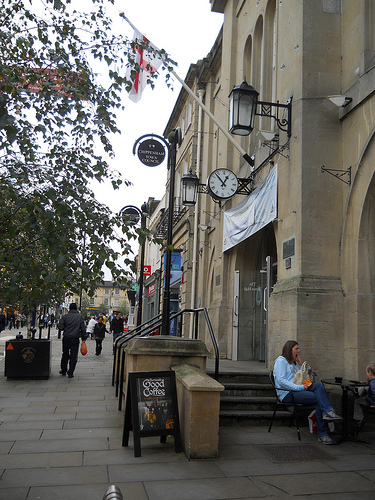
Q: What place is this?
A: It is a sidewalk.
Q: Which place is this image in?
A: It is at the sidewalk.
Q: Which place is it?
A: It is a sidewalk.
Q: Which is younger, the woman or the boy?
A: The boy is younger than the woman.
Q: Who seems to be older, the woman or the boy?
A: The woman is older than the boy.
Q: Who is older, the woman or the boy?
A: The woman is older than the boy.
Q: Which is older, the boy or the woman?
A: The woman is older than the boy.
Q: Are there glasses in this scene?
A: No, there are no glasses.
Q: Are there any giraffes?
A: No, there are no giraffes.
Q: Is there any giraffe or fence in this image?
A: No, there are no giraffes or fences.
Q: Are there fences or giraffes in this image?
A: No, there are no giraffes or fences.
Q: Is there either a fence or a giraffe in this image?
A: No, there are no giraffes or fences.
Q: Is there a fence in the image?
A: No, there are no fences.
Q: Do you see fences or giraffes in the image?
A: No, there are no fences or giraffes.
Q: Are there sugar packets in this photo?
A: No, there are no sugar packets.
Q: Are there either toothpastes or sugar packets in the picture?
A: No, there are no sugar packets or toothpastes.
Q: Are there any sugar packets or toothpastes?
A: No, there are no sugar packets or toothpastes.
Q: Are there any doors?
A: Yes, there is a door.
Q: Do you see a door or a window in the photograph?
A: Yes, there is a door.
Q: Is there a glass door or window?
A: Yes, there is a glass door.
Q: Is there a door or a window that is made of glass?
A: Yes, the door is made of glass.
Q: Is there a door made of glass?
A: Yes, there is a door that is made of glass.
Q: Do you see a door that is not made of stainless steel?
A: Yes, there is a door that is made of glass.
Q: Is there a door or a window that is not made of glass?
A: No, there is a door but it is made of glass.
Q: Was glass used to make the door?
A: Yes, the door is made of glass.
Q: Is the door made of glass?
A: Yes, the door is made of glass.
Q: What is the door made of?
A: The door is made of glass.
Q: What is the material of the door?
A: The door is made of glass.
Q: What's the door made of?
A: The door is made of glass.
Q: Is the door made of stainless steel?
A: No, the door is made of glass.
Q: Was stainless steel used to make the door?
A: No, the door is made of glass.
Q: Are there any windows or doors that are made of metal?
A: No, there is a door but it is made of glass.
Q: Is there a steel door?
A: No, there is a door but it is made of glass.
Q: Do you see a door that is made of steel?
A: No, there is a door but it is made of glass.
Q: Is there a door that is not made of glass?
A: No, there is a door but it is made of glass.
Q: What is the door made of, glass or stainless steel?
A: The door is made of glass.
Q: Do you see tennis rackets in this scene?
A: No, there are no tennis rackets.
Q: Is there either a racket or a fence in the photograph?
A: No, there are no rackets or fences.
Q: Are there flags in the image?
A: Yes, there is a flag.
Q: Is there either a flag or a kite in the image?
A: Yes, there is a flag.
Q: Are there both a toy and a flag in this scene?
A: No, there is a flag but no toys.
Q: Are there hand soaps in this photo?
A: No, there are no hand soaps.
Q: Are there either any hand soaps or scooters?
A: No, there are no hand soaps or scooters.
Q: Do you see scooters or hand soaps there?
A: No, there are no hand soaps or scooters.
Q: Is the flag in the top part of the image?
A: Yes, the flag is in the top of the image.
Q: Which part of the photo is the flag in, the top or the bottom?
A: The flag is in the top of the image.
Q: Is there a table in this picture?
A: Yes, there is a table.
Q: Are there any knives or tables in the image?
A: Yes, there is a table.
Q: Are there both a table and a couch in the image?
A: No, there is a table but no couches.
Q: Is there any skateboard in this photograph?
A: No, there are no skateboards.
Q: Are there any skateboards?
A: No, there are no skateboards.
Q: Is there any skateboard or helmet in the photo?
A: No, there are no skateboards or helmets.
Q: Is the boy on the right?
A: Yes, the boy is on the right of the image.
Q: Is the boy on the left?
A: No, the boy is on the right of the image.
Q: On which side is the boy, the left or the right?
A: The boy is on the right of the image.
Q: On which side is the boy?
A: The boy is on the right of the image.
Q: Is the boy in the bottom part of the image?
A: Yes, the boy is in the bottom of the image.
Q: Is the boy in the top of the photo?
A: No, the boy is in the bottom of the image.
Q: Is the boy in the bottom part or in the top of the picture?
A: The boy is in the bottom of the image.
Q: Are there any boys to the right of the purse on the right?
A: Yes, there is a boy to the right of the purse.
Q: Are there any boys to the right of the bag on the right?
A: Yes, there is a boy to the right of the purse.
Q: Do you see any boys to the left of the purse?
A: No, the boy is to the right of the purse.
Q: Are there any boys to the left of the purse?
A: No, the boy is to the right of the purse.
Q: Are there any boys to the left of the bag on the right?
A: No, the boy is to the right of the purse.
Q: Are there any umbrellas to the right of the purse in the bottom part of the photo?
A: No, there is a boy to the right of the purse.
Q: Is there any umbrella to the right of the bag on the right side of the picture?
A: No, there is a boy to the right of the purse.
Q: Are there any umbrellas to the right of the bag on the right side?
A: No, there is a boy to the right of the purse.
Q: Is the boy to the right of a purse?
A: Yes, the boy is to the right of a purse.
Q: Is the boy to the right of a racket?
A: No, the boy is to the right of a purse.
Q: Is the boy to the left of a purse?
A: No, the boy is to the right of a purse.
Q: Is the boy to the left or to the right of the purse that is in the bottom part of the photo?
A: The boy is to the right of the purse.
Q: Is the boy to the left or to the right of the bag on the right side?
A: The boy is to the right of the purse.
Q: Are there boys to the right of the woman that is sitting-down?
A: Yes, there is a boy to the right of the woman.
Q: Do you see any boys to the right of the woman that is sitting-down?
A: Yes, there is a boy to the right of the woman.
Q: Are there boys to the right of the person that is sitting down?
A: Yes, there is a boy to the right of the woman.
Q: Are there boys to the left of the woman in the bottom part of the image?
A: No, the boy is to the right of the woman.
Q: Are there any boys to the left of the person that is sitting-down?
A: No, the boy is to the right of the woman.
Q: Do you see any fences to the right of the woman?
A: No, there is a boy to the right of the woman.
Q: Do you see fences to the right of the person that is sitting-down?
A: No, there is a boy to the right of the woman.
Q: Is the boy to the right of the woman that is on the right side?
A: Yes, the boy is to the right of the woman.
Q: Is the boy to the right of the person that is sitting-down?
A: Yes, the boy is to the right of the woman.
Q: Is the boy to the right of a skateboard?
A: No, the boy is to the right of the woman.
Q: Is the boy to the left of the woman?
A: No, the boy is to the right of the woman.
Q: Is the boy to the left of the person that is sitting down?
A: No, the boy is to the right of the woman.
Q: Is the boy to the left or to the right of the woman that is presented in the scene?
A: The boy is to the right of the woman.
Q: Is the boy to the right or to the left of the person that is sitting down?
A: The boy is to the right of the woman.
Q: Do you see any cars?
A: No, there are no cars.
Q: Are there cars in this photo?
A: No, there are no cars.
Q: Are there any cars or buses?
A: No, there are no cars or buses.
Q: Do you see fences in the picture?
A: No, there are no fences.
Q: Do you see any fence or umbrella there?
A: No, there are no fences or umbrellas.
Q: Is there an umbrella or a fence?
A: No, there are no fences or umbrellas.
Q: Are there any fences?
A: No, there are no fences.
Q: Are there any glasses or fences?
A: No, there are no fences or glasses.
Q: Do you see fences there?
A: No, there are no fences.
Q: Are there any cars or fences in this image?
A: No, there are no fences or cars.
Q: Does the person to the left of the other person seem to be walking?
A: Yes, the person is walking.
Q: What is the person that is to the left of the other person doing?
A: The person is walking.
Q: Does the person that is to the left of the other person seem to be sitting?
A: No, the person is walking.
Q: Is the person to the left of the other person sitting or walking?
A: The person is walking.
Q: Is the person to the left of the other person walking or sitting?
A: The person is walking.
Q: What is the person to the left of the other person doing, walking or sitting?
A: The person is walking.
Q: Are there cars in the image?
A: No, there are no cars.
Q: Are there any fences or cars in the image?
A: No, there are no cars or fences.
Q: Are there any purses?
A: Yes, there is a purse.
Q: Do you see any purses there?
A: Yes, there is a purse.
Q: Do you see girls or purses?
A: Yes, there is a purse.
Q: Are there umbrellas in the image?
A: No, there are no umbrellas.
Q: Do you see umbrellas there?
A: No, there are no umbrellas.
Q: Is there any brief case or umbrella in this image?
A: No, there are no umbrellas or briefcases.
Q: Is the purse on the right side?
A: Yes, the purse is on the right of the image.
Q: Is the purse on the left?
A: No, the purse is on the right of the image.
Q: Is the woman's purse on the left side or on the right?
A: The purse is on the right of the image.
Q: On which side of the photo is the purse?
A: The purse is on the right of the image.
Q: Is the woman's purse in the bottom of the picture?
A: Yes, the purse is in the bottom of the image.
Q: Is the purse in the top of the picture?
A: No, the purse is in the bottom of the image.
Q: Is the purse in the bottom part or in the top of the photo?
A: The purse is in the bottom of the image.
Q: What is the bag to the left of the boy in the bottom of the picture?
A: The bag is a purse.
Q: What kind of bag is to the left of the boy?
A: The bag is a purse.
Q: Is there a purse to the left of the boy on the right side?
A: Yes, there is a purse to the left of the boy.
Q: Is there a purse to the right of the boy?
A: No, the purse is to the left of the boy.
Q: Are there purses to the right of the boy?
A: No, the purse is to the left of the boy.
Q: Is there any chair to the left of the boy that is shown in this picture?
A: No, there is a purse to the left of the boy.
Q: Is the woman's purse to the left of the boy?
A: Yes, the purse is to the left of the boy.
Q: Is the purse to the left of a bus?
A: No, the purse is to the left of the boy.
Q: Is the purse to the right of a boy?
A: No, the purse is to the left of a boy.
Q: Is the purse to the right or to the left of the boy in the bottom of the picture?
A: The purse is to the left of the boy.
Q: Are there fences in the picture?
A: No, there are no fences.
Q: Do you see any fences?
A: No, there are no fences.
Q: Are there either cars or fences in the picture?
A: No, there are no fences or cars.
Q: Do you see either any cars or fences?
A: No, there are no fences or cars.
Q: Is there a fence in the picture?
A: No, there are no fences.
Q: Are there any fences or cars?
A: No, there are no fences or cars.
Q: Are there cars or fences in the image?
A: No, there are no fences or cars.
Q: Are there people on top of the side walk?
A: Yes, there is a person on top of the side walk.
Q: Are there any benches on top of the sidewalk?
A: No, there is a person on top of the sidewalk.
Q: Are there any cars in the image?
A: No, there are no cars.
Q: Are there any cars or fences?
A: No, there are no cars or fences.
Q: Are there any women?
A: Yes, there is a woman.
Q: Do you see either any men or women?
A: Yes, there is a woman.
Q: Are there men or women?
A: Yes, there is a woman.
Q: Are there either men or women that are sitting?
A: Yes, the woman is sitting.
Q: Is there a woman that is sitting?
A: Yes, there is a woman that is sitting.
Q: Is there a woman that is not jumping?
A: Yes, there is a woman that is sitting.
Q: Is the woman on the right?
A: Yes, the woman is on the right of the image.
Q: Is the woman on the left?
A: No, the woman is on the right of the image.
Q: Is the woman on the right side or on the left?
A: The woman is on the right of the image.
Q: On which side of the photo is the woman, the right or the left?
A: The woman is on the right of the image.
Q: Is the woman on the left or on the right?
A: The woman is on the right of the image.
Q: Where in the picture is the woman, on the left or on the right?
A: The woman is on the right of the image.